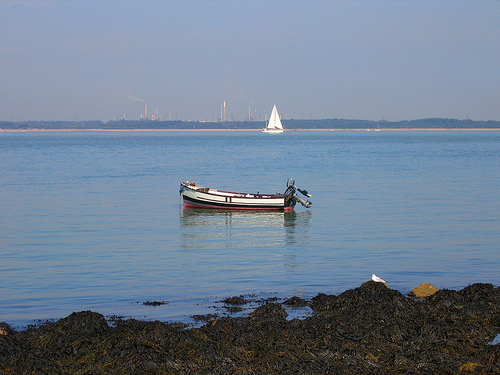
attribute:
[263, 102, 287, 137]
sailboat — white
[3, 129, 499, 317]
water — blue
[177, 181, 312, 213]
powerboat — red, whit, black,, wooden, floating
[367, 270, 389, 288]
bird — white, black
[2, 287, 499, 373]
seaweed — dark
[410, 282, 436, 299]
rock — brown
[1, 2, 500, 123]
sky — dark, cloudless, hazy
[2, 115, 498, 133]
shoreline — sandy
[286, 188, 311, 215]
engine — black, silver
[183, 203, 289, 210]
stripe — red